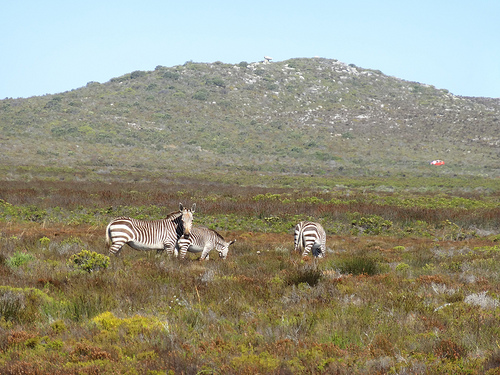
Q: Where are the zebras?
A: In a field.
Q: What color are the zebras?
A: White and black.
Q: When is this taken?
A: During the daytime.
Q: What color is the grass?
A: Green.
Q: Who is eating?
A: Zebras.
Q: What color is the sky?
A: Blue.